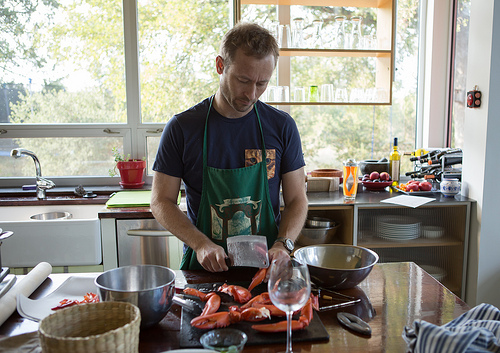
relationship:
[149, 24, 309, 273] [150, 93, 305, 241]
man wearing shirt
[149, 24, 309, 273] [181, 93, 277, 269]
man wearing apron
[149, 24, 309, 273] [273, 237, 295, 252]
man wearing watch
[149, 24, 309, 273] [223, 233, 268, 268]
man holding meat cleaver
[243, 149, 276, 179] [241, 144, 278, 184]
cat on shirt pocket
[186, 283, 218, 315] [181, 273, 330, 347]
lobster claw on cutting board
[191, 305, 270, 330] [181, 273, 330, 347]
lobster claw on cutting board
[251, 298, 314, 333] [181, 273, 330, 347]
lobster claw on cutting board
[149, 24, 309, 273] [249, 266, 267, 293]
man cracking lobster claw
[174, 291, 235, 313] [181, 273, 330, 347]
tongs on cutting board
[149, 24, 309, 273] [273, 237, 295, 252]
man has watch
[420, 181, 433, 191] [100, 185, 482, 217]
tomato on counter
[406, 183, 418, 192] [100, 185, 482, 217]
tomato on counter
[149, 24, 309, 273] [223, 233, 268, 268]
man has meat cleaver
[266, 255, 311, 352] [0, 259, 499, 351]
wine glass on counter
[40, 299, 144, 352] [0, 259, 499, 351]
basket on counter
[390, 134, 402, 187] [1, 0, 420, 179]
bottle of wine near window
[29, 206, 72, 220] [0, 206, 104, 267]
bowl in kitchen sink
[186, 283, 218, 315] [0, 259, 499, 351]
lobster claw on counter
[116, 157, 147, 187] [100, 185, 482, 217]
flower pot on counter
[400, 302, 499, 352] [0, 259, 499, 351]
towel on counter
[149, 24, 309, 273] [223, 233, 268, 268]
man using meat cleaver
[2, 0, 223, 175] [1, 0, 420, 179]
tree outside window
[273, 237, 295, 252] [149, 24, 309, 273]
watch on man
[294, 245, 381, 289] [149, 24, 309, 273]
bowl next to man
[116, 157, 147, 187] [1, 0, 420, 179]
flower pot by window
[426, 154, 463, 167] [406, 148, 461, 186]
bottle of wine in rack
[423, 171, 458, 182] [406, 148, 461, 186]
bottle of wine in rack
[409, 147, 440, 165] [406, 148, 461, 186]
bottle of wine in rack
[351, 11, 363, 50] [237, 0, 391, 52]
glass on shelf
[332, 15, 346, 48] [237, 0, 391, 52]
glass on shelf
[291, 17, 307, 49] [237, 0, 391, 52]
glass on shelf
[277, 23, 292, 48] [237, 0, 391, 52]
glass on shelf